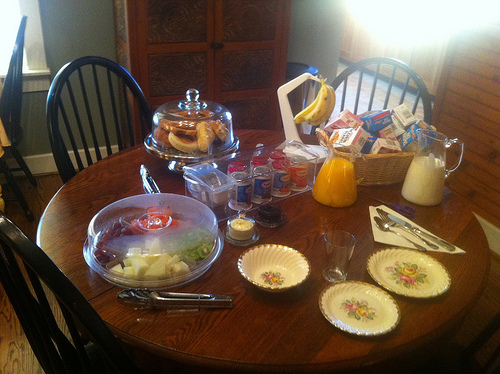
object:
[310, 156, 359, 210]
juice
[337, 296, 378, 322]
flowers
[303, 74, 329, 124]
bananas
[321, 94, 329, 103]
spots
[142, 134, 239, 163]
tray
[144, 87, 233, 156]
lid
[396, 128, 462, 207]
pitcher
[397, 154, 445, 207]
milk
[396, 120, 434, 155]
cereal boxes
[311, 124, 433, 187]
basket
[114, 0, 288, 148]
cabinet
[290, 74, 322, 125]
bananas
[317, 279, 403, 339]
plate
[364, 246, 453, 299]
plate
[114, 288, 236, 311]
tongs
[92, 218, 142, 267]
fruit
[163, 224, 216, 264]
fruit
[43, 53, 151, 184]
chair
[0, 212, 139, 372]
chair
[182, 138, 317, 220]
cold case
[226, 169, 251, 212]
yogurt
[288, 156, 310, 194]
yogurt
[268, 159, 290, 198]
yogurt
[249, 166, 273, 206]
yogurt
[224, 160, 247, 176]
yogurt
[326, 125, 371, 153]
cereal box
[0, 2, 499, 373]
dining room/chair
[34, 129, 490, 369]
kitchen table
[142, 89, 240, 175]
platter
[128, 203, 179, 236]
fruit/cheese tray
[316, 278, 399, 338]
floral plate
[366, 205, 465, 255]
silverware setting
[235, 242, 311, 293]
bowl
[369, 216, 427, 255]
shiny silverware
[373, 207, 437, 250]
silverware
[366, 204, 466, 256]
white napkin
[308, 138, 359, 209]
pitcher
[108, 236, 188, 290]
cheese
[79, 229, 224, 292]
tray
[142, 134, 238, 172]
dish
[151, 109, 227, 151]
bread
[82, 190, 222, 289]
lid